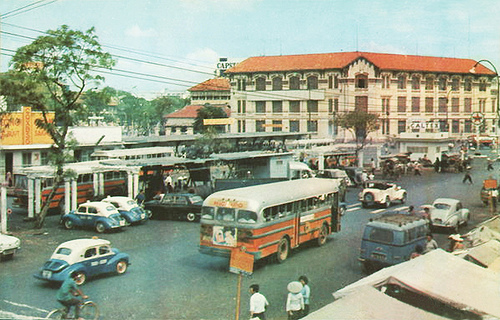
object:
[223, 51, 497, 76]
roof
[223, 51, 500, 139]
building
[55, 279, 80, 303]
shirt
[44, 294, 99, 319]
bike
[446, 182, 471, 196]
ground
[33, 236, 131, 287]
car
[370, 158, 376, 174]
people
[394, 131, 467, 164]
background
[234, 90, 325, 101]
wall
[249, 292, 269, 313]
shirt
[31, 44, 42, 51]
leaves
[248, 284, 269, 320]
man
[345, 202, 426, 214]
lines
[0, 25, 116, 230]
tree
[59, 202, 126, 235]
car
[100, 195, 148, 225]
car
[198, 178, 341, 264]
bus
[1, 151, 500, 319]
street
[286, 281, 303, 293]
hat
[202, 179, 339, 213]
top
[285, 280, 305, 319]
people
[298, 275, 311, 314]
people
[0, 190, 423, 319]
road way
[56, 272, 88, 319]
man